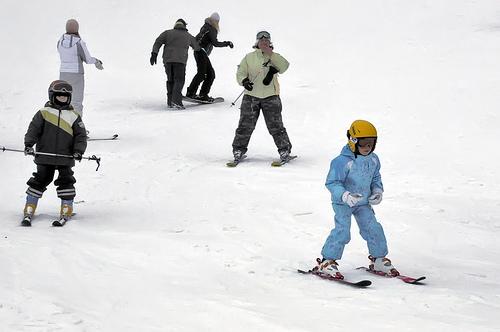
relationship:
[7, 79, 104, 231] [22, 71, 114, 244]
boy wearing snow suit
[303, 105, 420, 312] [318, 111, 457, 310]
boy wearing snow suit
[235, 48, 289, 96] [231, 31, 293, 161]
jacket is on people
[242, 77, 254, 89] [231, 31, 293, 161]
glove is on people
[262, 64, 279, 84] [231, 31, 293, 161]
glove is on people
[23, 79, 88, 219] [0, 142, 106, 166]
boy is holding ski pole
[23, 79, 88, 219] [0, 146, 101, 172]
boy is holding pole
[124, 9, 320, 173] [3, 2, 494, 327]
people is on slope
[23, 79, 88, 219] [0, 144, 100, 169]
boy carrying pole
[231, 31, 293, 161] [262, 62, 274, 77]
people removed glove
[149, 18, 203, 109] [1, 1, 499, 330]
people walking on snow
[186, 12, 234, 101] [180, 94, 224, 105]
person on snowboard snowboard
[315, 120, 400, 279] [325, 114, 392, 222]
boy wearing helmet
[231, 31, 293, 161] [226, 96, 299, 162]
people wearing pants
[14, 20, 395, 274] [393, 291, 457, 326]
people skiing in snow.